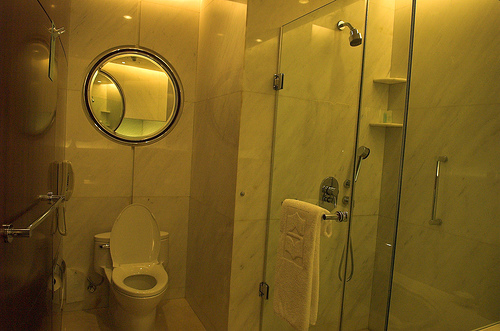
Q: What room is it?
A: It is a bathroom.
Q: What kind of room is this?
A: It is a bathroom.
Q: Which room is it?
A: It is a bathroom.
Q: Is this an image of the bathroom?
A: Yes, it is showing the bathroom.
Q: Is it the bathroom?
A: Yes, it is the bathroom.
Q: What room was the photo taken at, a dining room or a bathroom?
A: It was taken at a bathroom.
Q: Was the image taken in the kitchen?
A: No, the picture was taken in the bathroom.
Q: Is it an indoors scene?
A: Yes, it is indoors.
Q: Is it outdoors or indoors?
A: It is indoors.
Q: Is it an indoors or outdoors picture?
A: It is indoors.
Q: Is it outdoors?
A: No, it is indoors.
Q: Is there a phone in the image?
A: Yes, there is a phone.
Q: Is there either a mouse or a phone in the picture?
A: Yes, there is a phone.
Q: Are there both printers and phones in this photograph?
A: No, there is a phone but no printers.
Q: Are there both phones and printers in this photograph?
A: No, there is a phone but no printers.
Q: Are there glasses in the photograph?
A: No, there are no glasses.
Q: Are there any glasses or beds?
A: No, there are no glasses or beds.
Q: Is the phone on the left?
A: Yes, the phone is on the left of the image.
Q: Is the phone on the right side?
A: No, the phone is on the left of the image.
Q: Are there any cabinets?
A: No, there are no cabinets.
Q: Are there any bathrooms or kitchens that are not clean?
A: No, there is a bathroom but it is clean.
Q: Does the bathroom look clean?
A: Yes, the bathroom is clean.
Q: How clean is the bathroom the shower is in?
A: The bathroom is clean.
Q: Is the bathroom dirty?
A: No, the bathroom is clean.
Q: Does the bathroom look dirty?
A: No, the bathroom is clean.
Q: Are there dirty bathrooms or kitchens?
A: No, there is a bathroom but it is clean.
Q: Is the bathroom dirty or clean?
A: The bathroom is clean.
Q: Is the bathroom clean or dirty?
A: The bathroom is clean.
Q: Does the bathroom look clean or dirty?
A: The bathroom is clean.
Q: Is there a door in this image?
A: Yes, there are doors.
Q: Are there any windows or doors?
A: Yes, there are doors.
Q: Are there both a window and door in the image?
A: No, there are doors but no windows.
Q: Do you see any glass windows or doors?
A: Yes, there are glass doors.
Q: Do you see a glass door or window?
A: Yes, there are glass doors.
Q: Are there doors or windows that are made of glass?
A: Yes, the doors are made of glass.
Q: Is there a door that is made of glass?
A: Yes, there are doors that are made of glass.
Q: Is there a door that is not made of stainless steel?
A: Yes, there are doors that are made of glass.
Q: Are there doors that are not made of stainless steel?
A: Yes, there are doors that are made of glass.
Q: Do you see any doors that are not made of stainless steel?
A: Yes, there are doors that are made of glass.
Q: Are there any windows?
A: No, there are no windows.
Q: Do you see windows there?
A: No, there are no windows.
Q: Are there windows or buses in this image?
A: No, there are no windows or buses.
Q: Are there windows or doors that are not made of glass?
A: No, there are doors but they are made of glass.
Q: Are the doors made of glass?
A: Yes, the doors are made of glass.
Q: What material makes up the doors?
A: The doors are made of glass.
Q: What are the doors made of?
A: The doors are made of glass.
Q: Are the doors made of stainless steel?
A: No, the doors are made of glass.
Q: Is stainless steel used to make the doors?
A: No, the doors are made of glass.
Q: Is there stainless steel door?
A: No, there are doors but they are made of glass.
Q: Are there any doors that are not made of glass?
A: No, there are doors but they are made of glass.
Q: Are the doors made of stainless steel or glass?
A: The doors are made of glass.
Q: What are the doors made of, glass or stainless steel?
A: The doors are made of glass.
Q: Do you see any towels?
A: Yes, there is a towel.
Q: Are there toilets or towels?
A: Yes, there is a towel.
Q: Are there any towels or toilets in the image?
A: Yes, there is a towel.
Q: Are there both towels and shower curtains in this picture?
A: No, there is a towel but no shower curtains.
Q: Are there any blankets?
A: No, there are no blankets.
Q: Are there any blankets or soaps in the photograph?
A: No, there are no blankets or soaps.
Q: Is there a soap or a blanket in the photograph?
A: No, there are no blankets or soaps.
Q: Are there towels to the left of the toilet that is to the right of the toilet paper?
A: No, the towel is to the right of the toilet.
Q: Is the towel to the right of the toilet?
A: Yes, the towel is to the right of the toilet.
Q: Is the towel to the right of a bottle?
A: No, the towel is to the right of the toilet.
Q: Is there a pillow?
A: No, there are no pillows.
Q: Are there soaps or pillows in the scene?
A: No, there are no pillows or soaps.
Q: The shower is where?
A: The shower is in the bathroom.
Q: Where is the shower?
A: The shower is in the bathroom.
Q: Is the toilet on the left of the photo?
A: Yes, the toilet is on the left of the image.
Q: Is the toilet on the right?
A: No, the toilet is on the left of the image.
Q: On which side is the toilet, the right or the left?
A: The toilet is on the left of the image.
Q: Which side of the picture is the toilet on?
A: The toilet is on the left of the image.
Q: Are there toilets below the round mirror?
A: Yes, there is a toilet below the mirror.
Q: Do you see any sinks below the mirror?
A: No, there is a toilet below the mirror.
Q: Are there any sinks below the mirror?
A: No, there is a toilet below the mirror.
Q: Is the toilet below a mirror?
A: Yes, the toilet is below a mirror.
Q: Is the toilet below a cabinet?
A: No, the toilet is below a mirror.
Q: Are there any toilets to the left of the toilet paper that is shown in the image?
A: No, the toilet is to the right of the toilet paper.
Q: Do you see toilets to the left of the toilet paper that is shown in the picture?
A: No, the toilet is to the right of the toilet paper.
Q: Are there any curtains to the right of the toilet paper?
A: No, there is a toilet to the right of the toilet paper.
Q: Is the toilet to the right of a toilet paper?
A: Yes, the toilet is to the right of a toilet paper.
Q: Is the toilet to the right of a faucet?
A: No, the toilet is to the right of a toilet paper.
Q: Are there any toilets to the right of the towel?
A: No, the toilet is to the left of the towel.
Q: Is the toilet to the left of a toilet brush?
A: No, the toilet is to the left of the towel.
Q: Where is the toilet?
A: The toilet is in the bathroom.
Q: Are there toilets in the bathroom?
A: Yes, there is a toilet in the bathroom.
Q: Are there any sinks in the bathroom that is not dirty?
A: No, there is a toilet in the bathroom.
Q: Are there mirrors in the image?
A: Yes, there is a mirror.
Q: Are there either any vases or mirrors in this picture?
A: Yes, there is a mirror.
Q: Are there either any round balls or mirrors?
A: Yes, there is a round mirror.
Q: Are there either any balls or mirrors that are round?
A: Yes, the mirror is round.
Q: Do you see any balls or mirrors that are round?
A: Yes, the mirror is round.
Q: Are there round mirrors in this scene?
A: Yes, there is a round mirror.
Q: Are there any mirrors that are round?
A: Yes, there is a mirror that is round.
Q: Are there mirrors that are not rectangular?
A: Yes, there is a round mirror.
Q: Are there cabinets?
A: No, there are no cabinets.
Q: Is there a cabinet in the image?
A: No, there are no cabinets.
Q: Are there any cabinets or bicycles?
A: No, there are no cabinets or bicycles.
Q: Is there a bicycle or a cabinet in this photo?
A: No, there are no cabinets or bicycles.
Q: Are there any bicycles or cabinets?
A: No, there are no cabinets or bicycles.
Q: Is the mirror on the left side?
A: Yes, the mirror is on the left of the image.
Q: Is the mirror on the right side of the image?
A: No, the mirror is on the left of the image.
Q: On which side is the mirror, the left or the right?
A: The mirror is on the left of the image.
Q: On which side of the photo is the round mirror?
A: The mirror is on the left of the image.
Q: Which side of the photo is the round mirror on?
A: The mirror is on the left of the image.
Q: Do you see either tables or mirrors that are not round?
A: No, there is a mirror but it is round.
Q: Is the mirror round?
A: Yes, the mirror is round.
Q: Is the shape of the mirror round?
A: Yes, the mirror is round.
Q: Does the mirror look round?
A: Yes, the mirror is round.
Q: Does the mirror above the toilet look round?
A: Yes, the mirror is round.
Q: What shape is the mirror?
A: The mirror is round.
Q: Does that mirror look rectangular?
A: No, the mirror is round.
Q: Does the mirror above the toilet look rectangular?
A: No, the mirror is round.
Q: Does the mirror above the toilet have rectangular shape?
A: No, the mirror is round.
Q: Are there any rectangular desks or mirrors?
A: No, there is a mirror but it is round.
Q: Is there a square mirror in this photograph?
A: No, there is a mirror but it is round.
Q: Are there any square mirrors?
A: No, there is a mirror but it is round.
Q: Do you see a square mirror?
A: No, there is a mirror but it is round.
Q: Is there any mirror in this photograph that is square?
A: No, there is a mirror but it is round.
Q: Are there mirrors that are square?
A: No, there is a mirror but it is round.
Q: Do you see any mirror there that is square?
A: No, there is a mirror but it is round.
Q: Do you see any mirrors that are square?
A: No, there is a mirror but it is round.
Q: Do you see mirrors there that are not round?
A: No, there is a mirror but it is round.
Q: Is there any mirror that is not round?
A: No, there is a mirror but it is round.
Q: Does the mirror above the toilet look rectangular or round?
A: The mirror is round.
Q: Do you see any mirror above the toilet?
A: Yes, there is a mirror above the toilet.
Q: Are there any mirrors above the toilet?
A: Yes, there is a mirror above the toilet.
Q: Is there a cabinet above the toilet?
A: No, there is a mirror above the toilet.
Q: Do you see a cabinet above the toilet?
A: No, there is a mirror above the toilet.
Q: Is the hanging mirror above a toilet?
A: Yes, the mirror is above a toilet.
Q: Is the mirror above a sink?
A: No, the mirror is above a toilet.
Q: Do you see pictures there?
A: No, there are no pictures.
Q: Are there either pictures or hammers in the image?
A: No, there are no pictures or hammers.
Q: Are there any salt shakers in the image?
A: No, there are no salt shakers.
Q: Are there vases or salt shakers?
A: No, there are no salt shakers or vases.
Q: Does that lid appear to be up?
A: Yes, the lid is up.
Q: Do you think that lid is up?
A: Yes, the lid is up.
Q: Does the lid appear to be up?
A: Yes, the lid is up.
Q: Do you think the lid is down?
A: No, the lid is up.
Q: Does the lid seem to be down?
A: No, the lid is up.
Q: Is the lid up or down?
A: The lid is up.